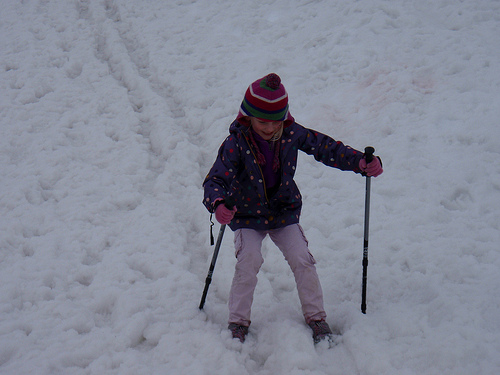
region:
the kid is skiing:
[144, 58, 420, 365]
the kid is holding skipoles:
[152, 130, 419, 372]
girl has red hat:
[223, 50, 286, 121]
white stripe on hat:
[218, 75, 282, 140]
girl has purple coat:
[205, 110, 335, 235]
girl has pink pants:
[237, 245, 319, 336]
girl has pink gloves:
[185, 191, 239, 233]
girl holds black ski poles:
[184, 143, 394, 370]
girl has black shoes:
[304, 275, 345, 372]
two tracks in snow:
[91, 21, 196, 232]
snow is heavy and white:
[21, 53, 133, 368]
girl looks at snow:
[210, 63, 287, 183]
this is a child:
[207, 77, 319, 317]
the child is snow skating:
[225, 71, 315, 321]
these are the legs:
[224, 245, 313, 323]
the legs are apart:
[233, 239, 320, 341]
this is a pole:
[349, 200, 383, 263]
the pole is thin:
[340, 195, 390, 268]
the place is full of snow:
[35, 260, 178, 372]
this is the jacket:
[231, 137, 293, 187]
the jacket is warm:
[230, 154, 294, 202]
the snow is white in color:
[103, 225, 175, 290]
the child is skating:
[188, 78, 358, 350]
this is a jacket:
[234, 153, 299, 191]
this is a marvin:
[240, 73, 287, 113]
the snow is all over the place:
[0, 110, 176, 334]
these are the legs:
[239, 237, 311, 314]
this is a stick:
[347, 197, 384, 267]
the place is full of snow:
[3, 150, 195, 346]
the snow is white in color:
[37, 223, 179, 373]